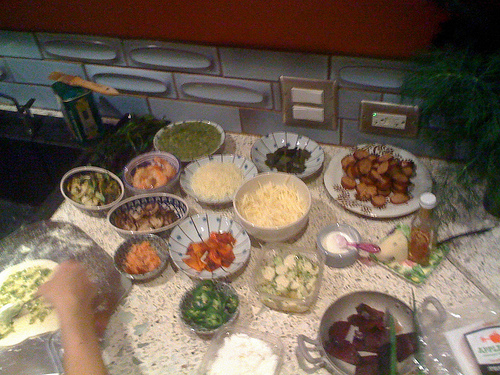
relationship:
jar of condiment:
[406, 190, 447, 270] [407, 207, 437, 264]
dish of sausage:
[321, 141, 438, 222] [340, 146, 418, 209]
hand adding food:
[40, 260, 104, 374] [2, 256, 61, 344]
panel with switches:
[4, 34, 457, 150] [279, 74, 340, 131]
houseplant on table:
[404, 38, 499, 219] [19, 114, 498, 373]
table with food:
[19, 114, 498, 373] [62, 123, 423, 373]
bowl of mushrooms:
[109, 193, 188, 235] [115, 203, 179, 232]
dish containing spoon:
[315, 221, 365, 267] [338, 233, 380, 262]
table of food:
[19, 114, 498, 373] [62, 123, 423, 373]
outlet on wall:
[357, 102, 423, 137] [4, 34, 457, 150]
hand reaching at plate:
[40, 260, 104, 374] [0, 217, 122, 368]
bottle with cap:
[410, 209, 442, 271] [417, 192, 437, 210]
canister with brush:
[53, 87, 108, 144] [47, 72, 121, 98]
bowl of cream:
[315, 223, 362, 265] [323, 233, 355, 254]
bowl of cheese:
[233, 171, 312, 240] [245, 176, 301, 225]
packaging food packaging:
[417, 303, 499, 373] [417, 303, 499, 373]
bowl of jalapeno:
[175, 281, 242, 336] [186, 276, 240, 327]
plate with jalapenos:
[175, 281, 242, 336] [186, 276, 240, 327]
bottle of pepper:
[410, 209, 442, 271] [407, 207, 437, 264]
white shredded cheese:
[244, 178, 303, 224] [245, 176, 301, 225]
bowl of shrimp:
[123, 151, 180, 194] [129, 156, 174, 188]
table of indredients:
[19, 114, 498, 373] [62, 123, 423, 373]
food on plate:
[340, 146, 418, 209] [321, 141, 438, 222]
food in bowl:
[328, 301, 414, 373] [298, 288, 447, 374]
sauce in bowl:
[159, 122, 220, 160] [154, 117, 225, 160]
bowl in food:
[116, 235, 170, 282] [123, 240, 161, 275]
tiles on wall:
[6, 32, 464, 153] [4, 34, 457, 150]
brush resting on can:
[47, 72, 121, 98] [53, 87, 108, 144]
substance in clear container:
[211, 330, 277, 374] [201, 325, 281, 374]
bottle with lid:
[410, 209, 442, 271] [417, 192, 437, 210]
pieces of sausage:
[345, 147, 419, 206] [340, 146, 418, 209]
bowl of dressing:
[315, 221, 365, 267] [323, 233, 355, 254]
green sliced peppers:
[187, 279, 237, 327] [186, 276, 240, 327]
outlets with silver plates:
[357, 102, 423, 137] [361, 100, 420, 136]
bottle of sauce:
[410, 209, 442, 271] [407, 207, 437, 264]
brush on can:
[47, 72, 121, 98] [53, 87, 108, 144]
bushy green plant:
[403, 43, 500, 218] [404, 38, 499, 219]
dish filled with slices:
[175, 281, 242, 336] [188, 290, 231, 328]